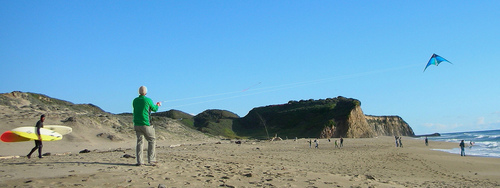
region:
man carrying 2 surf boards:
[2, 117, 79, 149]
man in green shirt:
[126, 79, 171, 172]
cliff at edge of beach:
[236, 89, 379, 140]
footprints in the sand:
[384, 146, 476, 186]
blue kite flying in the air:
[422, 48, 451, 78]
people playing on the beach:
[291, 134, 483, 159]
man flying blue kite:
[123, 42, 489, 110]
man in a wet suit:
[26, 113, 51, 165]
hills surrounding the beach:
[2, 84, 444, 140]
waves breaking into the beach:
[447, 130, 499, 147]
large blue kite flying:
[413, 46, 457, 80]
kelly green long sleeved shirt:
[117, 90, 164, 135]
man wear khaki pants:
[121, 78, 168, 168]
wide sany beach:
[76, 142, 439, 184]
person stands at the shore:
[439, 116, 496, 169]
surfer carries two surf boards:
[2, 109, 82, 167]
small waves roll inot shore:
[462, 123, 499, 151]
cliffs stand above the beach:
[171, 86, 488, 162]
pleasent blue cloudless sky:
[30, 4, 409, 81]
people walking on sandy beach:
[255, 124, 435, 156]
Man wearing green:
[113, 79, 175, 165]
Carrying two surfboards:
[18, 109, 76, 171]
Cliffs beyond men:
[241, 84, 419, 160]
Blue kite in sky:
[406, 45, 476, 75]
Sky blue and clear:
[4, 14, 495, 77]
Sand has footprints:
[83, 150, 381, 186]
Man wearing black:
[28, 109, 47, 154]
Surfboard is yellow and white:
[9, 129, 64, 141]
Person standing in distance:
[459, 135, 466, 162]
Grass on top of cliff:
[277, 95, 355, 102]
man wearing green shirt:
[121, 80, 171, 170]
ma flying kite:
[127, 51, 456, 166]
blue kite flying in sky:
[418, 50, 453, 70]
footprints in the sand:
[166, 140, 287, 185]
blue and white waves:
[405, 122, 496, 157]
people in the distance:
[298, 132, 348, 152]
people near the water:
[417, 132, 477, 157]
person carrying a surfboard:
[0, 105, 75, 161]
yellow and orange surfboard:
[0, 125, 61, 146]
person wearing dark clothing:
[23, 111, 53, 161]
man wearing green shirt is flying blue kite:
[126, 38, 451, 186]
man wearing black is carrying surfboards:
[2, 105, 71, 168]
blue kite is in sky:
[403, 41, 456, 85]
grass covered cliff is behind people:
[234, 88, 420, 152]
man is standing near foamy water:
[453, 131, 473, 158]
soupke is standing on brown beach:
[328, 132, 353, 155]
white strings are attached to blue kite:
[153, 50, 451, 110]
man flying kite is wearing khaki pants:
[115, 80, 170, 165]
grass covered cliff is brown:
[240, 95, 380, 140]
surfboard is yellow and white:
[10, 118, 67, 141]